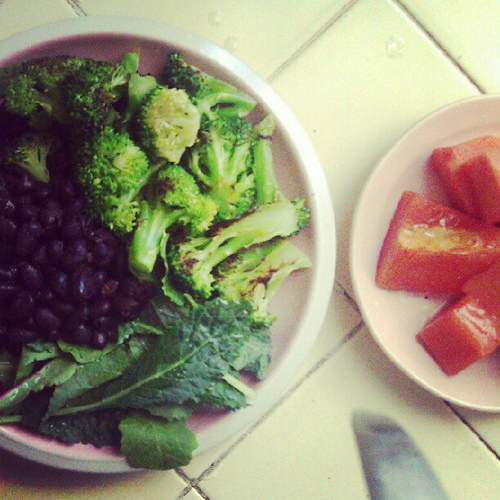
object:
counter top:
[0, 0, 499, 498]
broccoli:
[168, 51, 259, 123]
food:
[414, 264, 499, 376]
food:
[210, 239, 315, 331]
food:
[187, 112, 259, 220]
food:
[430, 135, 499, 225]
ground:
[273, 0, 500, 97]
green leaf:
[0, 297, 273, 470]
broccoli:
[80, 125, 168, 235]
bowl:
[0, 15, 337, 475]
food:
[10, 55, 88, 117]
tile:
[239, 432, 321, 489]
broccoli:
[127, 164, 219, 272]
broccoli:
[138, 85, 203, 165]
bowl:
[347, 93, 499, 415]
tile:
[196, 0, 292, 60]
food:
[375, 188, 499, 290]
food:
[0, 113, 57, 185]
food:
[0, 238, 87, 298]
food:
[250, 136, 310, 241]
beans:
[0, 290, 38, 326]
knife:
[348, 406, 446, 498]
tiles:
[408, 0, 499, 98]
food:
[166, 198, 300, 299]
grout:
[269, 0, 371, 64]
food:
[3, 134, 54, 185]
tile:
[293, 0, 470, 141]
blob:
[396, 219, 482, 252]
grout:
[399, 0, 488, 93]